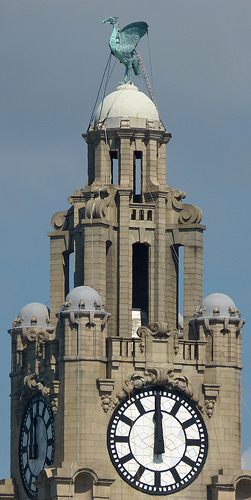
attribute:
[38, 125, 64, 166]
sky — bright, blue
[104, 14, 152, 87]
bird — green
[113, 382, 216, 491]
clock — large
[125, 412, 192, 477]
face — white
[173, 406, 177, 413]
marks — black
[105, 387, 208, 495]
clock — black, white, round, large, big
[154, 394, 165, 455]
hands — black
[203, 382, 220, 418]
shelf — small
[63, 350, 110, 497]
wall — grey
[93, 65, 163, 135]
top — roof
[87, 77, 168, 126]
top — roof, white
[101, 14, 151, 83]
monument — blue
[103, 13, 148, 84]
animal — blue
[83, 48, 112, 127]
straps — safety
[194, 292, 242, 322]
dome — small, gray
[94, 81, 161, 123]
dome — white, large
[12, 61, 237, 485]
tower — stone, clock, white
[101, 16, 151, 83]
sculpture — blue, animal, bird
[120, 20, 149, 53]
wing — blue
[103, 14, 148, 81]
statue — green, bronze, bird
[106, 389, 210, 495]
face — clock, black, white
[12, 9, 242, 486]
tower — large, monumental, clock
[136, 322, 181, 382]
details — curly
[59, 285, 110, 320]
detail — grey, domed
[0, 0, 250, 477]
sky — blue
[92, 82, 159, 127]
dome — white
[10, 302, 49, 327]
dome — gray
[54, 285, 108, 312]
dome — gray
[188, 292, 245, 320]
dome — gray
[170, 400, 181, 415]
line — black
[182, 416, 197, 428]
line — black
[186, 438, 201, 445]
line — black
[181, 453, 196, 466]
line — black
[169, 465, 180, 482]
line — black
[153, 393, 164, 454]
hands — pointing upward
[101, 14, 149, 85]
statue — large, bird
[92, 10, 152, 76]
bird — blue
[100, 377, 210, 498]
clock — big, black and white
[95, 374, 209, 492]
clock — very round, white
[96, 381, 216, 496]
clock — big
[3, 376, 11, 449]
sky — really blue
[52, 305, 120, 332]
designs — some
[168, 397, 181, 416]
bar — black, represents a number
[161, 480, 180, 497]
dots — white, represent seconds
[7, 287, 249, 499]
building — gray stone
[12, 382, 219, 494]
clocks — couple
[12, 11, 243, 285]
sky — blue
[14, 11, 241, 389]
scene — during the day time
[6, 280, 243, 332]
caps — some, blue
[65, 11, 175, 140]
bird — a statue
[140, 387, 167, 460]
hand — big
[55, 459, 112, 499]
arch — gray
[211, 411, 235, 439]
wall — stone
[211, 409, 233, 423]
wall — stone